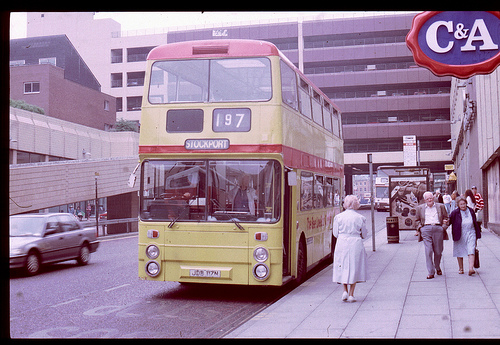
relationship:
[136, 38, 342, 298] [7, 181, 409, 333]
bus on street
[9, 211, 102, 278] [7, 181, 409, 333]
car on street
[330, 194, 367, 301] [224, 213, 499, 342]
woman on sidewalk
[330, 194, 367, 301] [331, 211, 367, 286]
woman has jacket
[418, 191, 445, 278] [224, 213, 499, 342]
man walking down sidewalk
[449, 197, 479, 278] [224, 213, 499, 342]
woman walking down sidewalk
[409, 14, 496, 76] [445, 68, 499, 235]
sign hanging on building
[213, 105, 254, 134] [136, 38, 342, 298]
sign on bus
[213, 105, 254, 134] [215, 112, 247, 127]
sign says 197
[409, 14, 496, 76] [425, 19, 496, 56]
sign has letters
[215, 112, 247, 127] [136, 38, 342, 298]
197 on bus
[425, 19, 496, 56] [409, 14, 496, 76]
letters on sign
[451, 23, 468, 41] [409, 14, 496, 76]
& sumbol on sign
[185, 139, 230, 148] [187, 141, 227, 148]
marquee says stockport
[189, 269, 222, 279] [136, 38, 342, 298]
license plate on bus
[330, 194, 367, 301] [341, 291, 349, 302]
woman has shoe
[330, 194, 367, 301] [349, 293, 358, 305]
woman has shoe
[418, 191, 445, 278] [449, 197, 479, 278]
man walking with woman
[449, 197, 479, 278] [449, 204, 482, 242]
woman has jacket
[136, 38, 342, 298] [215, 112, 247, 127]
bus has 197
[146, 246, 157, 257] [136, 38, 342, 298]
headlight on bus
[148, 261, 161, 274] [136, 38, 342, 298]
headlight on bus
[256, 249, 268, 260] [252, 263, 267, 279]
headlight next to headlight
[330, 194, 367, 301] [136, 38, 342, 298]
woman walking to bus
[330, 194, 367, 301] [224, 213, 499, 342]
woman walking down sidewalk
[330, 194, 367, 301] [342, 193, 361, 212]
woman has hair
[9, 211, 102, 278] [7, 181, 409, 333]
car driving down street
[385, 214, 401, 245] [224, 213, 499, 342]
trash can on sidewalk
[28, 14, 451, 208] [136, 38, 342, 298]
parking deck behind bus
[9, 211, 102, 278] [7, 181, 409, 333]
car driving on street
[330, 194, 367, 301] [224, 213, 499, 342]
woman walking on sidewalk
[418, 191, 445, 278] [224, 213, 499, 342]
man walking on sidewalk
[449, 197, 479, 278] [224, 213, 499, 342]
woman walking on sidewalk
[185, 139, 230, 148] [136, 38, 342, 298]
marquee on front of bus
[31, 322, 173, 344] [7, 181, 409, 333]
stop word on street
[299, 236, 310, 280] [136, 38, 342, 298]
tire on bus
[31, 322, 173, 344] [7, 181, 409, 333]
stop word painted on street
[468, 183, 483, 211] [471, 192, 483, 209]
man wears shirt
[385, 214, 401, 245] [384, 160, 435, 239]
trash can by bus stop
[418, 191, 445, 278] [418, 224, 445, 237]
man has hands in pockets